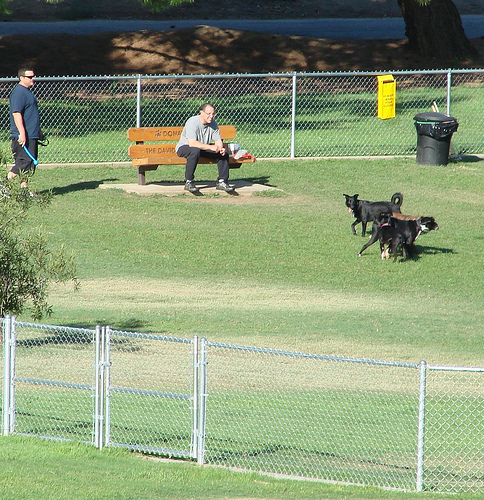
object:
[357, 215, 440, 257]
dogs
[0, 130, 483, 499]
field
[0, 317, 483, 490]
fence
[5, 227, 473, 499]
foreground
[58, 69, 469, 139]
shadow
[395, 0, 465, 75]
tree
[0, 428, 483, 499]
grass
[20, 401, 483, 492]
shadow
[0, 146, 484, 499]
ground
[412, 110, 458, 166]
trash can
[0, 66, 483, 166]
fence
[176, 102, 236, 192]
man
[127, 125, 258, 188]
bench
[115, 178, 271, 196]
dirt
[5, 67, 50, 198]
man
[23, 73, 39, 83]
sunglasses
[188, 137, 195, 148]
elbow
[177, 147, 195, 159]
lap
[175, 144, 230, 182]
pants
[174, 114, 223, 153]
shirt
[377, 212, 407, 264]
dog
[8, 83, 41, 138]
shirt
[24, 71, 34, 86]
face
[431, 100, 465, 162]
broom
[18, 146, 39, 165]
ball tosser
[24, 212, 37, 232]
leaves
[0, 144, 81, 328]
tree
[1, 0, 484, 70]
sidewalk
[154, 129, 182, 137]
engravings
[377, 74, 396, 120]
bag dispenser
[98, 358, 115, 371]
lock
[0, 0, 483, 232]
background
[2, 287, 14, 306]
branches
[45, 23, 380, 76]
dirt